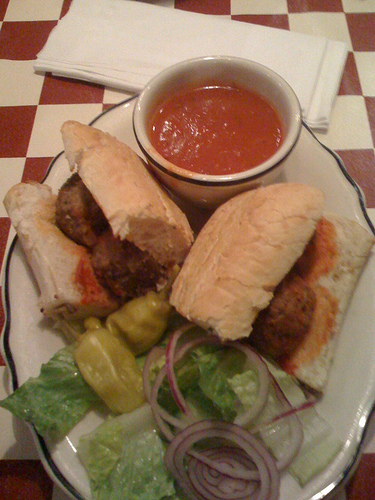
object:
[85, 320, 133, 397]
jalapeno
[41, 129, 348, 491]
plate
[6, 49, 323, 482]
food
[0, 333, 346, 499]
lettuce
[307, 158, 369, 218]
plate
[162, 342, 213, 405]
red onion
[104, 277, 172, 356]
pepper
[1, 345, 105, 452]
lettuce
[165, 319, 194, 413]
slice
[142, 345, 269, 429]
slice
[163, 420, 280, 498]
slice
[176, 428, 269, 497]
slice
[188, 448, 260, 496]
slice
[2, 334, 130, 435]
lettuce slice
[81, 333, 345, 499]
lettuce slice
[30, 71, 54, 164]
tablecloth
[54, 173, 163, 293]
meatballs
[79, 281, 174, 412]
peppers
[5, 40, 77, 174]
mat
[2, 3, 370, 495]
table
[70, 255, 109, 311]
sauce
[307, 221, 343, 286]
sauce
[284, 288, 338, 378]
sauce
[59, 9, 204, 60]
white napkins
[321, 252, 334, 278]
sauce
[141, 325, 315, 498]
slices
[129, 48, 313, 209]
bowl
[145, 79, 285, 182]
tomato sauce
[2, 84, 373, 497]
plate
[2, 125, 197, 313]
half sandwich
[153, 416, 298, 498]
onions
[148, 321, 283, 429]
onions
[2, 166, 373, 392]
sandwich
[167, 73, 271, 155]
sauce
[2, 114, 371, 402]
meatball sandwich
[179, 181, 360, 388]
bread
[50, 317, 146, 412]
pepper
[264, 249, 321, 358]
meatball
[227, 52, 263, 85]
part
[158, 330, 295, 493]
onion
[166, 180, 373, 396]
bread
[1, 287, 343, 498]
salad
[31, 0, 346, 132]
napkin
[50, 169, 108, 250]
meatball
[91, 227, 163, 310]
meatball